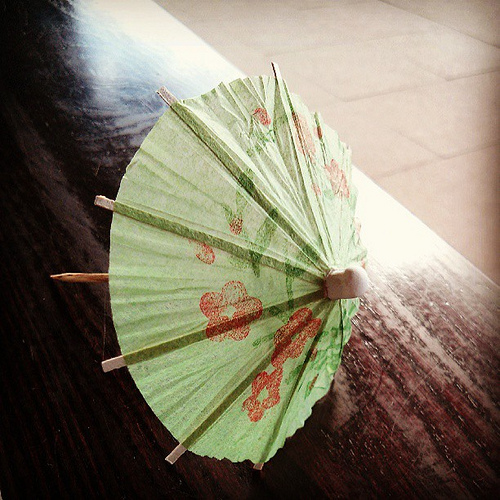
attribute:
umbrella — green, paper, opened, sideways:
[49, 60, 368, 470]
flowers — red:
[187, 107, 351, 421]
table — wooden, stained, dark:
[0, 0, 499, 500]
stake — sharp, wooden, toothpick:
[49, 271, 109, 283]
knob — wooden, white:
[327, 264, 368, 300]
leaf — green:
[223, 171, 321, 303]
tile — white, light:
[156, 0, 499, 284]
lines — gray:
[223, 2, 499, 180]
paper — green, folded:
[108, 74, 368, 464]